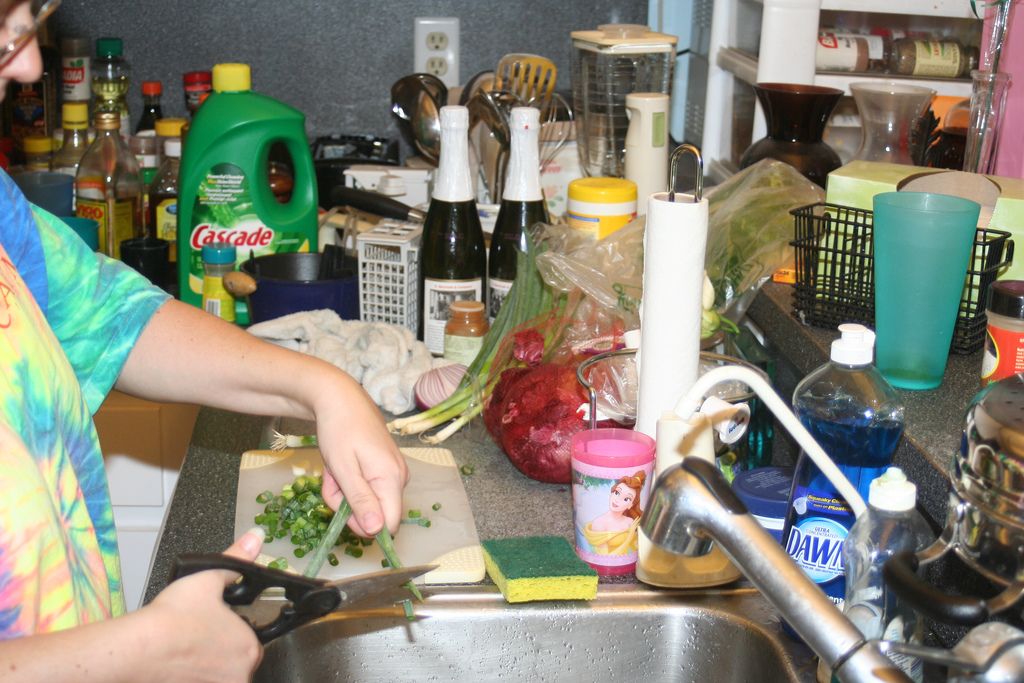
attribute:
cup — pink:
[571, 430, 657, 574]